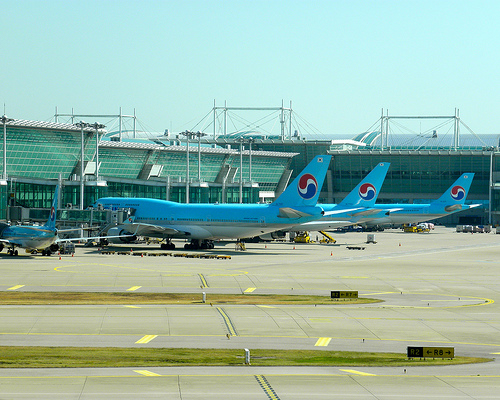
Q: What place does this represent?
A: It represents the airport.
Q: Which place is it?
A: It is an airport.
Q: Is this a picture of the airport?
A: Yes, it is showing the airport.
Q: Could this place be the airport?
A: Yes, it is the airport.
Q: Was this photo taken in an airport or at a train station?
A: It was taken at an airport.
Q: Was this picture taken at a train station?
A: No, the picture was taken in an airport.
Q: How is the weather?
A: It is cloudless.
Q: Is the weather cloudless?
A: Yes, it is cloudless.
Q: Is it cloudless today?
A: Yes, it is cloudless.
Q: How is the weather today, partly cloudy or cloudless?
A: It is cloudless.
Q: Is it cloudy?
A: No, it is cloudless.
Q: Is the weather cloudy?
A: No, it is cloudless.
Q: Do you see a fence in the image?
A: No, there are no fences.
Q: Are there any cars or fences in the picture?
A: No, there are no fences or cars.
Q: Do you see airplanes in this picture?
A: Yes, there is an airplane.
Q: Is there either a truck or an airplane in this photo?
A: Yes, there is an airplane.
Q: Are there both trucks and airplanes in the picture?
A: No, there is an airplane but no trucks.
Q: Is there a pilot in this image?
A: No, there are no pilots.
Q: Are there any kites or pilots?
A: No, there are no pilots or kites.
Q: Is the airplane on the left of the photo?
A: Yes, the airplane is on the left of the image.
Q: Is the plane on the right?
A: No, the plane is on the left of the image.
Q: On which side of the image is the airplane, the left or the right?
A: The airplane is on the left of the image.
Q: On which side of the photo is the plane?
A: The plane is on the left of the image.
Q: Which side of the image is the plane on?
A: The plane is on the left of the image.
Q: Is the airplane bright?
A: Yes, the airplane is bright.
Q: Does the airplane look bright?
A: Yes, the airplane is bright.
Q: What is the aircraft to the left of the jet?
A: The aircraft is an airplane.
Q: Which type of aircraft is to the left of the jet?
A: The aircraft is an airplane.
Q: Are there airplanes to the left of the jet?
A: Yes, there is an airplane to the left of the jet.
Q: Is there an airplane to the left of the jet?
A: Yes, there is an airplane to the left of the jet.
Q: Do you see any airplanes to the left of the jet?
A: Yes, there is an airplane to the left of the jet.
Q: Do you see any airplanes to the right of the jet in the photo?
A: No, the airplane is to the left of the jet.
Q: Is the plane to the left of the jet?
A: Yes, the plane is to the left of the jet.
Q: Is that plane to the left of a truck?
A: No, the plane is to the left of the jet.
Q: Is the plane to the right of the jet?
A: No, the plane is to the left of the jet.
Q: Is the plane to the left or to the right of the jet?
A: The plane is to the left of the jet.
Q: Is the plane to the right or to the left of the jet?
A: The plane is to the left of the jet.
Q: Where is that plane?
A: The plane is at the terminal.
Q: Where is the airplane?
A: The plane is at the terminal.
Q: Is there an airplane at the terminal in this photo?
A: Yes, there is an airplane at the terminal.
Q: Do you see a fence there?
A: No, there are no fences.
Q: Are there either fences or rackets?
A: No, there are no fences or rackets.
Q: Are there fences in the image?
A: No, there are no fences.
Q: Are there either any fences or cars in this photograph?
A: No, there are no fences or cars.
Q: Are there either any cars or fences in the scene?
A: No, there are no fences or cars.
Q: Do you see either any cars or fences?
A: No, there are no fences or cars.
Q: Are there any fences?
A: No, there are no fences.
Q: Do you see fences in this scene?
A: No, there are no fences.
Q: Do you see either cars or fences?
A: No, there are no fences or cars.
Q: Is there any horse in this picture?
A: No, there are no horses.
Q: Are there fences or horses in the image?
A: No, there are no horses or fences.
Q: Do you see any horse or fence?
A: No, there are no horses or fences.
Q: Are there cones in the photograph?
A: No, there are no cones.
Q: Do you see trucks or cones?
A: No, there are no cones or trucks.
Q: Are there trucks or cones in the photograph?
A: No, there are no cones or trucks.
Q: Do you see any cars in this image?
A: No, there are no cars.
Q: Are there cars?
A: No, there are no cars.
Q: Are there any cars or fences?
A: No, there are no cars or fences.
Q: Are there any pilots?
A: No, there are no pilots.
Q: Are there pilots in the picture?
A: No, there are no pilots.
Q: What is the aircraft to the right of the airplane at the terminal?
A: The aircraft is a jet.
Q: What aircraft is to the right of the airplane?
A: The aircraft is a jet.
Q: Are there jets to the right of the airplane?
A: Yes, there is a jet to the right of the airplane.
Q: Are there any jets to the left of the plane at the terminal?
A: No, the jet is to the right of the plane.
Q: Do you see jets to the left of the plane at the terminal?
A: No, the jet is to the right of the plane.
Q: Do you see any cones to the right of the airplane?
A: No, there is a jet to the right of the airplane.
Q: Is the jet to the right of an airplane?
A: Yes, the jet is to the right of an airplane.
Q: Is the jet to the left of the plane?
A: No, the jet is to the right of the plane.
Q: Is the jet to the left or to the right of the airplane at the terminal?
A: The jet is to the right of the airplane.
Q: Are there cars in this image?
A: No, there are no cars.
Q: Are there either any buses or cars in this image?
A: No, there are no cars or buses.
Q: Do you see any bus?
A: No, there are no buses.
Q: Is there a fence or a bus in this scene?
A: No, there are no buses or fences.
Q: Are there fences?
A: No, there are no fences.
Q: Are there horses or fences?
A: No, there are no fences or horses.